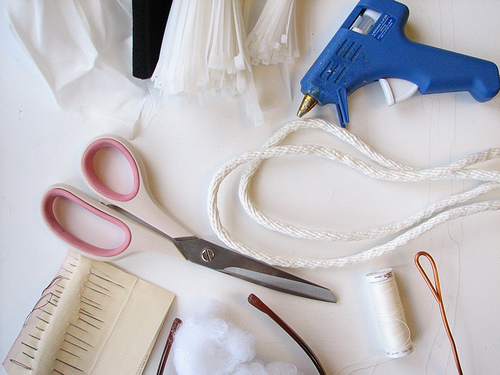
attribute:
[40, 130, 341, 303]
scissors — pink, white, these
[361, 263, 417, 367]
thread — white, in the photo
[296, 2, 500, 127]
glue gun — blue, hot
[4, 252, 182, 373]
needles — different sizes, in photo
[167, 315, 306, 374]
cotton — in a ball, a ball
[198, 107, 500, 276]
rope — white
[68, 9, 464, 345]
craft supples — arts, crafts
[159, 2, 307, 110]
plastic ties — in a bunch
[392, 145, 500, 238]
cord — white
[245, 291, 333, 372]
eyeglasses — on table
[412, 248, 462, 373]
wick — in photo, in the photo, cooper, gold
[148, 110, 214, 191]
surface — white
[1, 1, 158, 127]
cloth — photo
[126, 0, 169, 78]
blades — silver, black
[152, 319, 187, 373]
frame — red